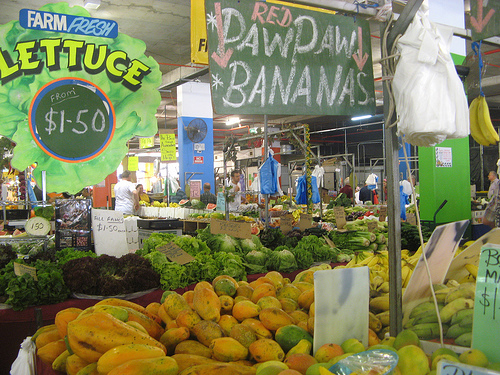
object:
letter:
[61, 38, 81, 71]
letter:
[122, 56, 150, 90]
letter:
[82, 44, 104, 72]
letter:
[105, 51, 129, 79]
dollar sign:
[44, 105, 57, 135]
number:
[72, 109, 89, 135]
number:
[91, 108, 107, 132]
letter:
[224, 59, 252, 108]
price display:
[24, 80, 122, 159]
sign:
[205, 3, 374, 109]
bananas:
[367, 256, 379, 266]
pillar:
[417, 0, 472, 225]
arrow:
[210, 2, 233, 69]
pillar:
[2, 6, 167, 195]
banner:
[205, 3, 376, 109]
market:
[0, 0, 500, 375]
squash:
[208, 337, 248, 361]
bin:
[9, 321, 475, 375]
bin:
[11, 234, 161, 312]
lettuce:
[64, 250, 155, 296]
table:
[135, 227, 189, 250]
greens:
[264, 248, 300, 272]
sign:
[194, 142, 206, 152]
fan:
[185, 118, 208, 142]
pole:
[381, 16, 403, 336]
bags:
[396, 10, 469, 148]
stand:
[391, 12, 474, 39]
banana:
[469, 96, 492, 147]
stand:
[446, 26, 484, 58]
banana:
[478, 94, 498, 146]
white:
[249, 65, 269, 109]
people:
[113, 169, 139, 215]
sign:
[0, 0, 165, 194]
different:
[5, 190, 500, 375]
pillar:
[176, 81, 215, 198]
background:
[0, 0, 500, 375]